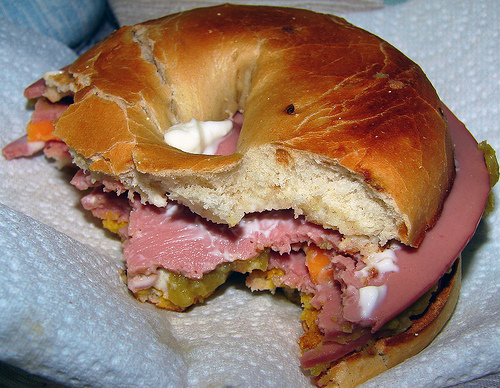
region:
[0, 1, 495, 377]
bagel is half eaten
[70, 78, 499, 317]
bologna on the bagel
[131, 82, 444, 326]
mayonaise on the bagel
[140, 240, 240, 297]
pickle on the bagel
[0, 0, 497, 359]
bagel on a paper towel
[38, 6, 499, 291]
the bread is brown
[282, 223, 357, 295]
orange food on bologna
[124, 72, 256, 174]
hole in center of bagel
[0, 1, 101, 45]
blue design on bagel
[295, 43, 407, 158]
creases in the bread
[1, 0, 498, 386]
The sandwich is on a piece of paper.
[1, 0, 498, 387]
The paper is white.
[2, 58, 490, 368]
The sandwich has meat on it.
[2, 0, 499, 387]
The sandwich has been half eaten.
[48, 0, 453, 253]
The bun is brown.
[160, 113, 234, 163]
The sandwich has a white sauce on it.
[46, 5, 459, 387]
The bread is a bagel.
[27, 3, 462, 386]
The sandwich is thick.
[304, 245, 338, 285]
The sandwich has something orange in it.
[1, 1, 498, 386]
The sandwich is on paper.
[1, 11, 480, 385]
partially eaten sandwich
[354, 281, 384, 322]
white sauce on the meat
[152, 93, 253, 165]
hole in the bead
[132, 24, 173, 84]
crack in the bread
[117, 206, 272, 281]
pink meat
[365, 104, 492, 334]
thin slice of meat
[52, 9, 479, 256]
thick piece of bread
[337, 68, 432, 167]
dark brown spot on the bread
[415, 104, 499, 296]
meat hanging out of the bun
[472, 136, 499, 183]
bit of green food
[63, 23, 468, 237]
A half of sandwich on a napkin.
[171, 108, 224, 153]
The sandwich has mayonaisse on it.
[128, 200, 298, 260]
The sandwich have ham on it.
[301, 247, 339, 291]
Yellow cheese on the sandwich.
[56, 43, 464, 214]
A sandwich made on a bagel.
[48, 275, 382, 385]
The napkin is white.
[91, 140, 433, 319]
A piece of sandwich is missing.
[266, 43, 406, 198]
The bagel is toasted.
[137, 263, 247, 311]
Pickle on the sandwich.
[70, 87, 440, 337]
Half of the sandwich was eaten.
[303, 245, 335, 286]
Something orange is on the snadwich.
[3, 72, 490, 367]
Meat is on the sandwich.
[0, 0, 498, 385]
The sandwich is on a napkin.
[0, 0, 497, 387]
The napkin is made of paper.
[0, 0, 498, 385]
The napkin is white.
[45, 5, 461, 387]
The bun is a bagel.